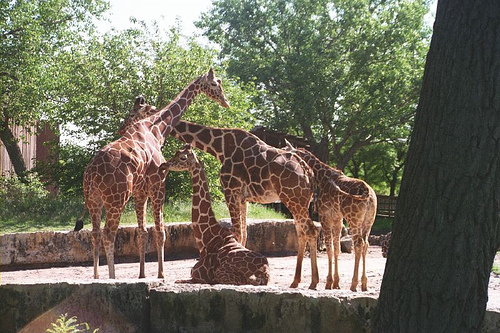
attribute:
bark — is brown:
[425, 142, 454, 166]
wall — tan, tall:
[0, 227, 70, 271]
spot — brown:
[103, 172, 115, 188]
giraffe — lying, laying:
[157, 144, 274, 288]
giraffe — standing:
[72, 63, 235, 280]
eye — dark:
[178, 152, 189, 163]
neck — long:
[159, 85, 200, 130]